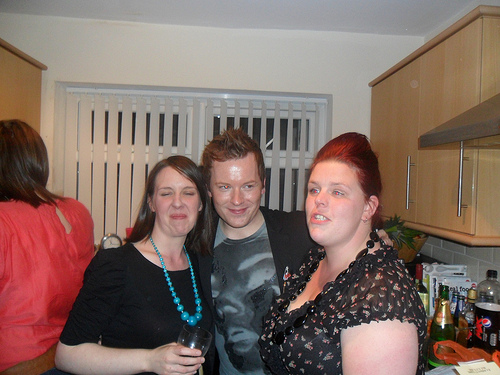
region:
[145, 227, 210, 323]
the blue plastic necklace of the woman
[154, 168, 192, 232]
the face of the woman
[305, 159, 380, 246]
the face of the woman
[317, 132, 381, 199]
the red hair of the woman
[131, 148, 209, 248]
the brown hair of the woman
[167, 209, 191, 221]
the mouth of the woman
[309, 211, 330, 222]
the mouth of the woman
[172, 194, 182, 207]
the nose of the woman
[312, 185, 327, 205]
the nose of the woman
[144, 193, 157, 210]
the ear of the woman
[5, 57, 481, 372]
people gathered in a kitchen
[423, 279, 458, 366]
a bottle of sparkling wine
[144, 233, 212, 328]
a blue faux-pearl necklace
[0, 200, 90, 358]
woman wearing a red shirt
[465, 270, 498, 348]
a plastic bottle of Pepsi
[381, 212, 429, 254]
leaf of a green plant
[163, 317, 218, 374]
woman holding a glass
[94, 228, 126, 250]
a silver clock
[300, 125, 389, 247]
a red-headed woman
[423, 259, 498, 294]
cookbooks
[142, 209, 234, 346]
the woman is wearing a necklace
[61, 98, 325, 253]
the blinds are white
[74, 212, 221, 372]
the woman is holding a glass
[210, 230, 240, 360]
the shirt is gray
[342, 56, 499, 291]
the cabinets are closed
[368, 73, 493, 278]
the cabinet is made of wood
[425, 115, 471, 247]
the handle is silver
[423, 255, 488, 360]
the bottle is open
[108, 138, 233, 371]
the woman is wearing necklace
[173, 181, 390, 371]
the man is wearing a coat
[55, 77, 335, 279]
window with white window blinds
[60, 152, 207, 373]
woman wearing a black dress and blue necklace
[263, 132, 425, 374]
woman wearing a black floral print dress and black necklace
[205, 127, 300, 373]
man with light brown hair wearing black jacket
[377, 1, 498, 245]
wooden kitchen cabinets with silver handles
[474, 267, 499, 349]
half empty bottle of pepsi max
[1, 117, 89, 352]
the back view of a woman wearing a red shirt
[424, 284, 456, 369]
open bottle of champaign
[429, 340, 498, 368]
an orange plastic shopping bag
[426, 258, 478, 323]
an assortment of cook books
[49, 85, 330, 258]
white vertical blinds partially open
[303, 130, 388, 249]
bright red hair pulled back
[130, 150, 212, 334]
eyes closed in photo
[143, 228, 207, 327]
woman wears big blue necklace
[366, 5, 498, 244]
tan wooden cabinets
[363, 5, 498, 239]
tan cabinets with silver handles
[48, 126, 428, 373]
one man between two women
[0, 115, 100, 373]
partial view of woman's back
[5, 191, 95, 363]
salmon-colored blouse with hole in back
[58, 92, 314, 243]
photo taken at night